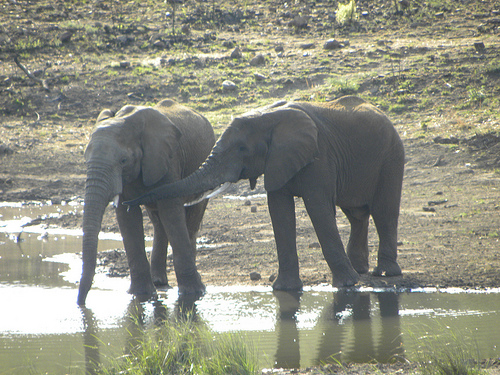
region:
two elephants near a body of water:
[51, 69, 449, 344]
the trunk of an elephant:
[55, 185, 115, 308]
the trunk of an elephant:
[106, 153, 233, 213]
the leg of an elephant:
[266, 195, 302, 300]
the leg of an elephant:
[306, 198, 367, 299]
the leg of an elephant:
[113, 210, 158, 302]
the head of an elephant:
[206, 108, 325, 205]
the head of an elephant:
[79, 111, 154, 204]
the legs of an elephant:
[261, 195, 410, 306]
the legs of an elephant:
[112, 208, 218, 300]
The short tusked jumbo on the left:
[65, 96, 210, 303]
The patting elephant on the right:
[121, 95, 406, 286]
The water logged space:
[0, 195, 496, 370]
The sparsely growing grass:
[5, 0, 495, 120]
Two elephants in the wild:
[0, 0, 496, 374]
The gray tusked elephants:
[67, 97, 402, 302]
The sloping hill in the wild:
[0, 0, 495, 374]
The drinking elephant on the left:
[56, 95, 216, 305]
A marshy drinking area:
[0, 201, 497, 372]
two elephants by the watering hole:
[41, 73, 418, 315]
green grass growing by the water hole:
[95, 325, 221, 374]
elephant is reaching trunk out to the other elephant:
[110, 143, 264, 215]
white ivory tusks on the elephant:
[202, 176, 238, 203]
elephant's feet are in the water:
[110, 265, 213, 303]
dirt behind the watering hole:
[414, 180, 471, 280]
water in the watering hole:
[12, 246, 42, 311]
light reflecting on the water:
[5, 285, 70, 329]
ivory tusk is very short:
[108, 189, 124, 211]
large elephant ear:
[265, 109, 340, 195]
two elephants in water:
[48, 90, 412, 322]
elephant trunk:
[74, 188, 104, 310]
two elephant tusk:
[178, 175, 238, 212]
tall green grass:
[77, 295, 248, 374]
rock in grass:
[238, 259, 266, 282]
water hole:
[3, 196, 498, 373]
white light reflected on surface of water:
[5, 235, 319, 354]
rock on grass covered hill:
[213, 69, 250, 96]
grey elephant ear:
[264, 106, 326, 198]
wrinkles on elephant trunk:
[83, 158, 105, 205]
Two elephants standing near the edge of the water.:
[29, 38, 429, 343]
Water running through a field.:
[11, 211, 491, 373]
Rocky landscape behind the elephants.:
[10, 1, 478, 271]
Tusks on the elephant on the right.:
[180, 175, 234, 210]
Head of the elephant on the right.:
[207, 100, 310, 186]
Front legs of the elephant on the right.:
[262, 195, 353, 300]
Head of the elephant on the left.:
[68, 89, 168, 204]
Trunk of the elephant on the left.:
[70, 151, 112, 306]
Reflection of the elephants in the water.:
[53, 288, 420, 368]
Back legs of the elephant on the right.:
[344, 193, 402, 283]